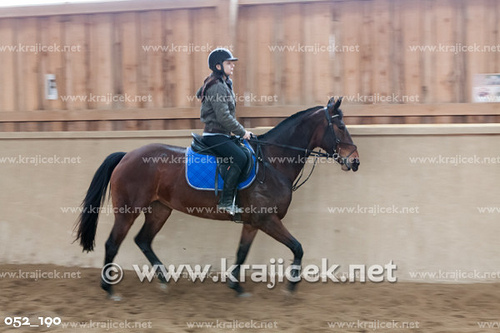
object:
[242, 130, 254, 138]
hand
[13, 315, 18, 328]
number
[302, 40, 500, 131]
window blinds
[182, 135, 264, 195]
pad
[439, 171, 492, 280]
wall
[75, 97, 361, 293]
horse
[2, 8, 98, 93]
wall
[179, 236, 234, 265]
wall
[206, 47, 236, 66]
helmet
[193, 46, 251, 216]
person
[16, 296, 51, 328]
dirt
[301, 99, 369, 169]
head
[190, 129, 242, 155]
saddle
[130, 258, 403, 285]
website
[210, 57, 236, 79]
head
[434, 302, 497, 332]
dirt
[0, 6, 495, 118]
fence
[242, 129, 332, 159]
horse reign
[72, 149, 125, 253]
tail